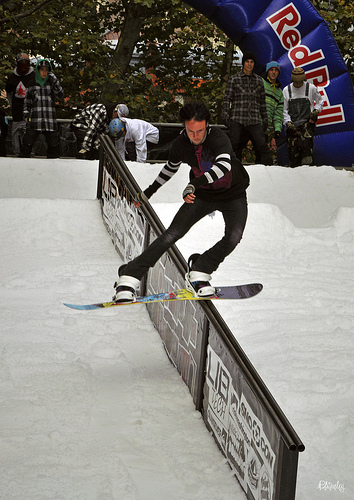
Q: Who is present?
A: People.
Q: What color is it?
A: White.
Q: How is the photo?
A: Clear.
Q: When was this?
A: Daytime.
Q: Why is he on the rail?
A: Doing a stunt.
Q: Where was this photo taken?
A: On a ski slope.